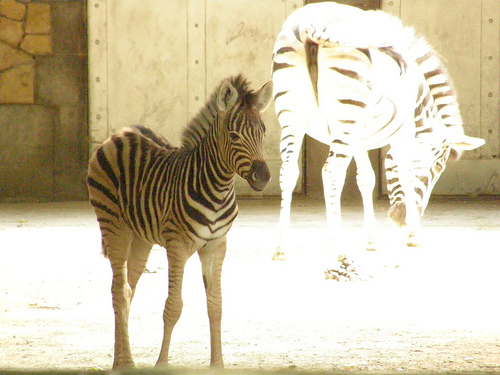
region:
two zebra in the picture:
[84, 0, 486, 372]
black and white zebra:
[83, 73, 275, 373]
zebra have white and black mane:
[182, 75, 253, 157]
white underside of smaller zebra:
[108, 220, 226, 370]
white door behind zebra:
[85, 3, 305, 197]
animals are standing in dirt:
[1, 191, 498, 373]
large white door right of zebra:
[382, 0, 499, 196]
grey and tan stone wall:
[1, 0, 88, 197]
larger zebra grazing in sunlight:
[271, 2, 481, 231]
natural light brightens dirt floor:
[0, 211, 499, 366]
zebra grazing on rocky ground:
[269, 1, 485, 258]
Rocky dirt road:
[3, 193, 497, 373]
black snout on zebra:
[245, 160, 270, 192]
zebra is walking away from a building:
[85, 75, 273, 372]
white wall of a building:
[90, 0, 497, 200]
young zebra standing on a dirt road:
[83, 70, 273, 370]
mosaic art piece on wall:
[1, 0, 51, 105]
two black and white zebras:
[83, 0, 485, 372]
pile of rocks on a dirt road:
[322, 250, 364, 288]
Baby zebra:
[20, 44, 284, 372]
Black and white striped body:
[104, 133, 207, 230]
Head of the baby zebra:
[202, 75, 282, 210]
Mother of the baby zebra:
[272, 11, 487, 269]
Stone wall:
[0, 9, 65, 83]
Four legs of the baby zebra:
[102, 257, 248, 373]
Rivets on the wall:
[83, 38, 120, 130]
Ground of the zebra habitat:
[273, 286, 484, 358]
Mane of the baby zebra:
[180, 82, 214, 145]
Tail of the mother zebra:
[297, 40, 337, 115]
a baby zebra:
[69, 90, 289, 367]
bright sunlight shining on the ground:
[366, 277, 449, 327]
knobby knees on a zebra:
[156, 295, 240, 335]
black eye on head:
[224, 122, 251, 145]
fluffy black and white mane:
[180, 106, 222, 138]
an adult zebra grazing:
[279, 15, 468, 247]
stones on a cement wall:
[6, 11, 52, 102]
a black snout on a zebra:
[248, 154, 274, 201]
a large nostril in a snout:
[246, 171, 264, 183]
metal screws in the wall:
[83, 10, 112, 91]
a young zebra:
[96, 79, 268, 373]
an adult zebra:
[282, 13, 472, 225]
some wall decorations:
[0, 7, 57, 101]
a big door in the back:
[91, 0, 278, 179]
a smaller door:
[380, 3, 495, 196]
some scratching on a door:
[200, 16, 270, 68]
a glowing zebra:
[259, 13, 476, 243]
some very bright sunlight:
[5, 218, 494, 332]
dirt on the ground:
[5, 216, 484, 346]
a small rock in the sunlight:
[290, 258, 364, 303]